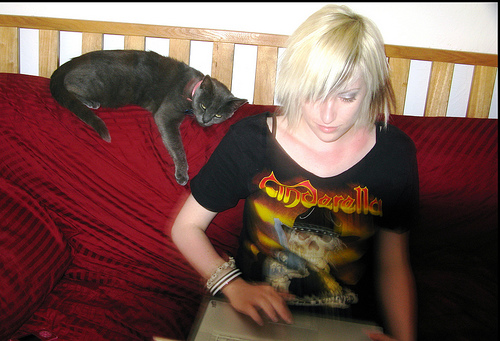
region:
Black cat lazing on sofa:
[48, 48, 248, 187]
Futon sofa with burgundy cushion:
[0, 12, 498, 337]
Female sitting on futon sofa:
[170, 2, 415, 337]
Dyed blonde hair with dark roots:
[270, 1, 395, 132]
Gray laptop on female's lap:
[150, 296, 380, 336]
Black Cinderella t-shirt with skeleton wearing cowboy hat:
[185, 110, 417, 325]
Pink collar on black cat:
[185, 75, 200, 101]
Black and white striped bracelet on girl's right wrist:
[205, 265, 240, 295]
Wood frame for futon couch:
[0, 15, 498, 120]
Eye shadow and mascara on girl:
[338, 90, 362, 103]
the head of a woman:
[271, 43, 403, 178]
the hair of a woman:
[273, 19, 425, 139]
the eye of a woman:
[307, 85, 370, 117]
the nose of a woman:
[315, 103, 342, 138]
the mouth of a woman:
[305, 110, 355, 163]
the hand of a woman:
[200, 259, 313, 331]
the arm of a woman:
[136, 53, 311, 296]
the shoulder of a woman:
[181, 88, 309, 219]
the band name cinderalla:
[261, 171, 386, 218]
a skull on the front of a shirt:
[287, 229, 337, 264]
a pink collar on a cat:
[188, 78, 205, 105]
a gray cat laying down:
[52, 48, 248, 185]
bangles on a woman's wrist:
[196, 258, 239, 298]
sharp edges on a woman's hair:
[275, 79, 305, 132]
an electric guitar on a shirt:
[258, 276, 354, 315]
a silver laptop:
[142, 289, 387, 339]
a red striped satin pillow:
[0, 178, 72, 340]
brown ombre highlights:
[370, 73, 397, 128]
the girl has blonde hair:
[280, 9, 392, 132]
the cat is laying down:
[53, 47, 236, 189]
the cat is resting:
[52, 48, 251, 188]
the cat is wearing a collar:
[188, 70, 205, 112]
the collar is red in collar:
[191, 75, 207, 99]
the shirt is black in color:
[200, 114, 408, 325]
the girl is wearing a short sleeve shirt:
[200, 105, 425, 320]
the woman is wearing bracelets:
[205, 258, 245, 300]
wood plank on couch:
[36, 24, 65, 76]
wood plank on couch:
[81, 32, 113, 55]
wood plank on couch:
[122, 32, 147, 50]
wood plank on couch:
[166, 37, 200, 77]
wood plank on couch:
[206, 44, 244, 94]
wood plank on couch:
[249, 42, 294, 118]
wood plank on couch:
[384, 56, 413, 138]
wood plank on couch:
[426, 65, 447, 125]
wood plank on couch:
[464, 62, 491, 122]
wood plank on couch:
[2, 27, 24, 75]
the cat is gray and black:
[47, 46, 237, 181]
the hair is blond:
[279, 6, 396, 111]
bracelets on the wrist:
[200, 258, 246, 298]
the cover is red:
[0, 73, 497, 333]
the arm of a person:
[172, 195, 220, 268]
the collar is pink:
[183, 73, 205, 100]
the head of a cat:
[190, 80, 245, 125]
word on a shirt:
[257, 167, 394, 220]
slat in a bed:
[170, 35, 190, 72]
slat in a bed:
[123, 34, 146, 51]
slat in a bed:
[80, 28, 103, 56]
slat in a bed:
[32, 29, 62, 76]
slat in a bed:
[1, 30, 18, 73]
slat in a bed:
[254, 45, 281, 108]